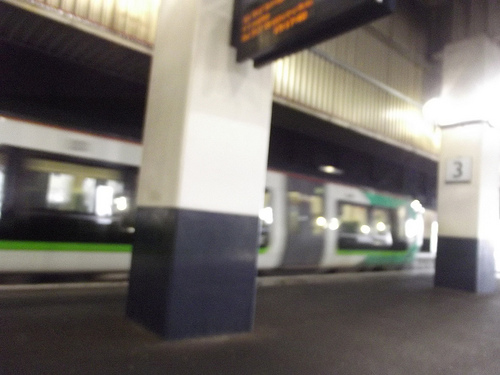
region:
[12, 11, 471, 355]
Picture taken indoors.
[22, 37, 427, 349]
Picture is blurry.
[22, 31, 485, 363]
Not focusing on anything.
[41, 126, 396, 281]
A subway train.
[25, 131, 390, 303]
The train is white green and grey.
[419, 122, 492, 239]
The number 3 on the wall.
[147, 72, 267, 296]
The column is white and grey.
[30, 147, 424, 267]
Large windows on the train.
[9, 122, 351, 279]
Many windows on the train.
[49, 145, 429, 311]
The train is moving.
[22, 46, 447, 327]
white, green, and black subway train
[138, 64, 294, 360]
black and white column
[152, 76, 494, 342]
two black and white columns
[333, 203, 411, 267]
windows of subway car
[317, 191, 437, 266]
light reflecting off subway car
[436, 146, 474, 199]
sign on column says 3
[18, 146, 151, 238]
window on subway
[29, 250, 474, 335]
platform of train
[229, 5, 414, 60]
arrival and departure sign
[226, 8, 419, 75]
electronic sign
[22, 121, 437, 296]
One train is running.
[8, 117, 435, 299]
Train is white and green color.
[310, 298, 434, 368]
Floor is grey color.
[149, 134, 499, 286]
Two pillar is seen.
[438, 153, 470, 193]
Number 3 board is seen in pillar.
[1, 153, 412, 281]
Windows are in sides of the train.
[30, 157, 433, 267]
Light reflection is seen in train.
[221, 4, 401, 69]
Board is black color.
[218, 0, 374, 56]
Letters are orange color.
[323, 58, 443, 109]
Shed is grey color.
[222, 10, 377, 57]
sign hanging on post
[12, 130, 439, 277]
train is passing by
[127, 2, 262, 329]
post is white and black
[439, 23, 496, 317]
post has a number on it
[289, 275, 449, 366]
cement waiting area is grey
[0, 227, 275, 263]
green stripe on train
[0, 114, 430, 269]
train is blurry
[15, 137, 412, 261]
windows on train reflecting light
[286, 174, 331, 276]
grey doors on train are shut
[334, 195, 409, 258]
windows of train have black border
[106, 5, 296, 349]
a structural column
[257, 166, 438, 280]
a train car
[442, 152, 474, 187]
a sign labeled with number 3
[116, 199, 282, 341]
a portion of a column painted blue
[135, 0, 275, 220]
a portion of a column painted white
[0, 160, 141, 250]
a window on a train car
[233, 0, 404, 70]
an informational display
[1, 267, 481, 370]
a train platform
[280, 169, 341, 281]
a train door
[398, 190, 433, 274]
a reflection off of a train car